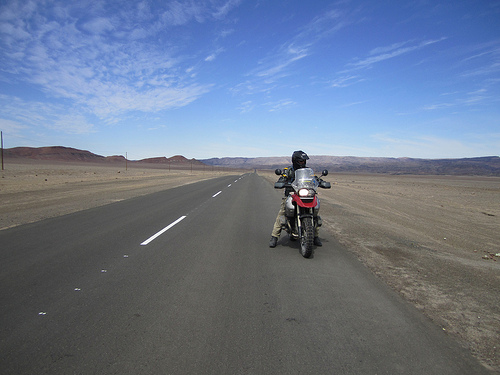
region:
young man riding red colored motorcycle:
[266, 139, 333, 233]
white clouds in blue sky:
[6, 0, 78, 51]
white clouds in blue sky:
[10, 39, 84, 96]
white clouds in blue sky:
[20, 92, 105, 144]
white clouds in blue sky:
[116, 80, 207, 150]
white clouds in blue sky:
[84, 32, 174, 87]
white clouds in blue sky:
[193, 12, 317, 67]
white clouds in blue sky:
[199, 35, 299, 103]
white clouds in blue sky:
[303, 0, 390, 54]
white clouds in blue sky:
[339, 32, 467, 109]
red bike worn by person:
[257, 150, 327, 246]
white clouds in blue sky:
[13, 102, 93, 131]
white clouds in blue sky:
[197, 0, 259, 88]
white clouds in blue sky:
[180, 94, 268, 125]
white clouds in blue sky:
[285, 32, 423, 100]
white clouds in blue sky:
[397, 46, 467, 114]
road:
[98, 207, 204, 297]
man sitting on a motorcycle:
[269, 149, 323, 246]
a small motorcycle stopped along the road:
[274, 167, 326, 257]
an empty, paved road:
[1, 168, 493, 373]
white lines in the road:
[24, 173, 246, 335]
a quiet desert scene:
[1, 160, 499, 373]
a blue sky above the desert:
[1, 0, 499, 160]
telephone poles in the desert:
[0, 129, 221, 174]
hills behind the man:
[2, 145, 499, 172]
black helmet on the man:
[291, 148, 308, 165]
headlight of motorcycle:
[299, 187, 311, 194]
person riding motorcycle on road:
[250, 146, 319, 253]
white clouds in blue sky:
[6, 45, 52, 100]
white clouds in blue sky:
[395, 24, 490, 143]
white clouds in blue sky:
[276, 83, 369, 136]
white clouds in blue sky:
[209, 78, 274, 139]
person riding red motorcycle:
[258, 127, 341, 268]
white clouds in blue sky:
[14, 17, 87, 67]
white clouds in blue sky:
[92, 18, 182, 58]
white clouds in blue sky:
[99, 89, 199, 126]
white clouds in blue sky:
[218, 63, 311, 119]